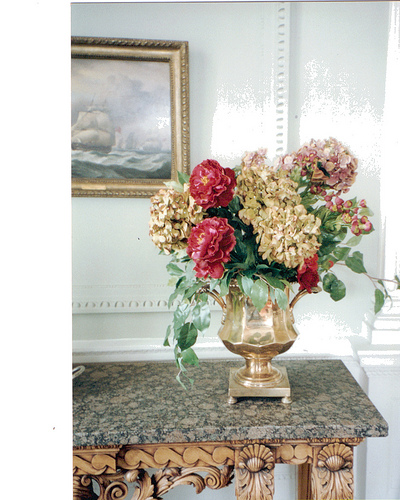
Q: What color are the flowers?
A: Red Pink and yellow.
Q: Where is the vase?
A: ON the table.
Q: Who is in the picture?
A: No one.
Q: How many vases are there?
A: 1.